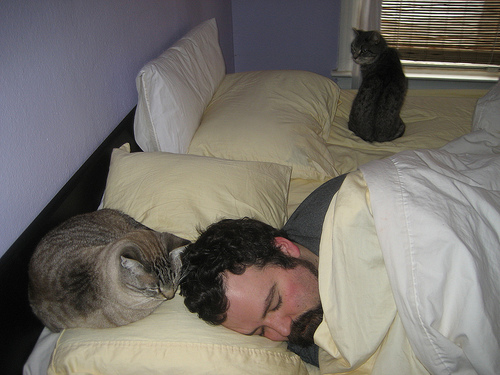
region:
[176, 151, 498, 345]
A man asleep in a bed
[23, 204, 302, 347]
A cat by mans head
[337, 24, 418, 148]
a cat sitting on a bed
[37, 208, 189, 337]
A tan cat on a pillow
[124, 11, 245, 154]
A white pillow by the wall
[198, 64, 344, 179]
a yellow pillow on the bed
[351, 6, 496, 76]
a window in front of the cat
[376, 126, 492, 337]
a white blanket on the bed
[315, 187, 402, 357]
a yellow sheet on the bed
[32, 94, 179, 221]
a black headboard by the wall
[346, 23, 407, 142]
A thin tabby cat on a bed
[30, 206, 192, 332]
A large tabby cat on a pillow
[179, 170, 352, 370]
A man sleeping in a bed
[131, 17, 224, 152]
A large white pillow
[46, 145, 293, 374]
A large yellow pillow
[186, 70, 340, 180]
A large yellow pillow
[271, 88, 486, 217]
some yellow sheets on a bed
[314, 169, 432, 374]
some yellow sheets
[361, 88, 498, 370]
some white blankets on the bed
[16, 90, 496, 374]
A large bed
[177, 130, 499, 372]
a sleeping man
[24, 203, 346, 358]
the cat is laying above the man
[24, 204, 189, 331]
the cat is gray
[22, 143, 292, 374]
the cat is laying on the pillow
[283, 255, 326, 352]
the man has a beard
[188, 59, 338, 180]
the pillow is cream colored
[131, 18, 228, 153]
the pillow is white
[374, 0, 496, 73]
the window blinds are brown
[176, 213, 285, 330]
the man has curly dark hair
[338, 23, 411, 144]
a cat is sitting on the other side of the bed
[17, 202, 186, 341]
cat on a bed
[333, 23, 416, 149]
cat on a bed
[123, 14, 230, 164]
pillow on a bed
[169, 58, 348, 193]
pillow on a bed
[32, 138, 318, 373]
pillow on a bed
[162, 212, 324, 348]
head of a person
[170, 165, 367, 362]
person is sleeping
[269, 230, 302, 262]
ear of a person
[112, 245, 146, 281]
ear of a cat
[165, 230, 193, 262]
ear of a cat on the bed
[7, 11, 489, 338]
two cats on a bed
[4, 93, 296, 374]
a cat laying on a bed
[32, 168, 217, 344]
a cat laying on a pillow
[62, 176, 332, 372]
a cat laying by a man's head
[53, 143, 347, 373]
a cat laying at the top of a man's head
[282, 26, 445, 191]
a cat sitting on a bed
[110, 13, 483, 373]
two cats that are inside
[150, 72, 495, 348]
a man laying in bed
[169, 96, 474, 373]
a man sleeping in bed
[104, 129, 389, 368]
a man sleeping on a pillow